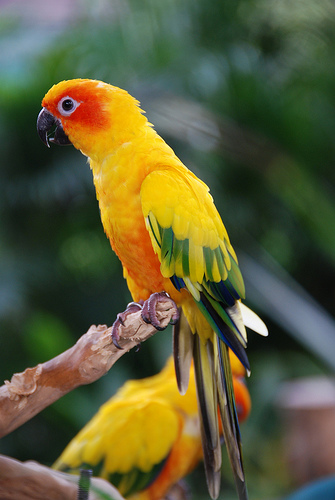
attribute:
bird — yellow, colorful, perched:
[36, 75, 271, 493]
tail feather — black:
[191, 324, 227, 497]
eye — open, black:
[57, 93, 84, 119]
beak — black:
[33, 108, 71, 155]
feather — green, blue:
[159, 226, 177, 267]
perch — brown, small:
[1, 291, 174, 446]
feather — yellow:
[186, 224, 209, 290]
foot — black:
[138, 288, 178, 331]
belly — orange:
[102, 223, 168, 295]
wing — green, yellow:
[141, 162, 258, 380]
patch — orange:
[44, 84, 115, 133]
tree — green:
[2, 3, 335, 500]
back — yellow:
[145, 114, 231, 242]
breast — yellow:
[82, 152, 146, 225]